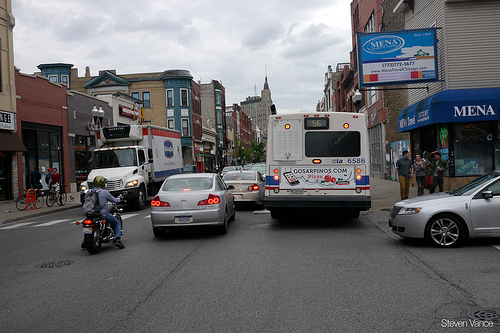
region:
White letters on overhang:
[451, 103, 497, 118]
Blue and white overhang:
[396, 84, 499, 132]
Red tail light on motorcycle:
[81, 219, 93, 226]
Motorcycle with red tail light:
[75, 194, 127, 256]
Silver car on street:
[148, 171, 238, 236]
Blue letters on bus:
[331, 159, 343, 164]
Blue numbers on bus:
[347, 157, 365, 165]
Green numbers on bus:
[311, 118, 323, 129]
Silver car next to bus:
[148, 102, 374, 241]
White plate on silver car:
[176, 215, 191, 223]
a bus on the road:
[205, 85, 365, 241]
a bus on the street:
[262, 48, 457, 291]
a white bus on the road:
[272, 81, 396, 280]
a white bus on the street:
[272, 58, 400, 320]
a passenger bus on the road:
[239, 41, 449, 288]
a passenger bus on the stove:
[214, 49, 404, 294]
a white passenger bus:
[271, 76, 429, 326]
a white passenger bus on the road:
[225, 61, 419, 309]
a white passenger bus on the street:
[234, 63, 371, 280]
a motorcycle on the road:
[57, 148, 112, 263]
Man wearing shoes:
[72, 234, 139, 252]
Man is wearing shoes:
[80, 233, 126, 250]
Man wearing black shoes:
[80, 231, 123, 251]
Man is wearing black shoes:
[76, 233, 128, 252]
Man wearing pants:
[101, 208, 122, 242]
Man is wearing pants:
[100, 212, 125, 238]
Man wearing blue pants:
[87, 205, 124, 238]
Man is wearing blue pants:
[97, 209, 124, 239]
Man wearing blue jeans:
[95, 209, 128, 241]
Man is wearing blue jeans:
[97, 209, 127, 241]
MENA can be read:
[356, 26, 436, 68]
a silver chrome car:
[388, 187, 480, 255]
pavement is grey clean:
[221, 231, 387, 328]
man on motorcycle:
[78, 191, 143, 266]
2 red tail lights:
[146, 188, 235, 240]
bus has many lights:
[249, 90, 374, 221]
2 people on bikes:
[16, 159, 77, 221]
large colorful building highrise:
[40, 50, 237, 186]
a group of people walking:
[376, 134, 451, 224]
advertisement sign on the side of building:
[352, 27, 440, 87]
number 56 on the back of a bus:
[301, 115, 331, 129]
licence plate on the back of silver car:
[170, 212, 197, 227]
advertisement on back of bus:
[280, 162, 356, 191]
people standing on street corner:
[395, 148, 443, 196]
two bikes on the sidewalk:
[14, 186, 68, 211]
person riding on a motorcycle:
[71, 171, 126, 251]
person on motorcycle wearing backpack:
[80, 188, 101, 218]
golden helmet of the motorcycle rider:
[92, 173, 107, 189]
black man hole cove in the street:
[28, 256, 80, 273]